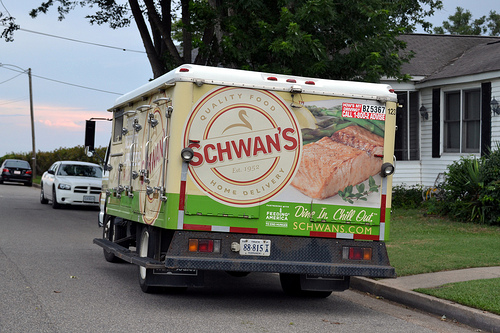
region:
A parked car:
[40, 159, 107, 204]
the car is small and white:
[40, 159, 106, 206]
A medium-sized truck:
[98, 83, 395, 298]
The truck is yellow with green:
[101, 76, 396, 301]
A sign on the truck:
[189, 88, 389, 211]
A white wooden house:
[379, 31, 499, 212]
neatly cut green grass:
[387, 207, 499, 302]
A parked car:
[2, 156, 29, 185]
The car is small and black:
[0, 157, 32, 184]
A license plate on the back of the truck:
[234, 236, 275, 257]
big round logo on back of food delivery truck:
[184, 88, 300, 205]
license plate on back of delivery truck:
[237, 235, 272, 259]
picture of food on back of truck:
[298, 139, 383, 195]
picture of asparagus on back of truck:
[297, 101, 340, 142]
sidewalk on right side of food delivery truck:
[398, 260, 498, 305]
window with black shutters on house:
[429, 84, 496, 161]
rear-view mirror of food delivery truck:
[80, 111, 112, 161]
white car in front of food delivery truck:
[39, 157, 102, 214]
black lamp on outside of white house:
[417, 101, 434, 125]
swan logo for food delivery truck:
[223, 105, 257, 132]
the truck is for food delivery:
[78, 63, 403, 301]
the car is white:
[33, 153, 111, 218]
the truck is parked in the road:
[83, 60, 406, 302]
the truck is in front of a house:
[76, 61, 401, 299]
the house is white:
[354, 67, 499, 210]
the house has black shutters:
[389, 81, 497, 160]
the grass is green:
[358, 203, 499, 327]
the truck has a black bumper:
[155, 227, 400, 284]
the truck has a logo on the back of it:
[180, 83, 303, 209]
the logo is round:
[184, 77, 301, 209]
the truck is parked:
[76, 47, 426, 316]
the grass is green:
[410, 221, 452, 274]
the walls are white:
[414, 85, 496, 172]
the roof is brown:
[403, 37, 491, 85]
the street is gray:
[3, 211, 106, 321]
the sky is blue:
[24, 34, 80, 81]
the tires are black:
[96, 214, 185, 314]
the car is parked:
[29, 146, 124, 230]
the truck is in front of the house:
[61, 29, 478, 326]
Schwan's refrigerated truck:
[95, 60, 430, 317]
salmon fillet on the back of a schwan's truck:
[293, 127, 385, 205]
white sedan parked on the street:
[35, 153, 108, 218]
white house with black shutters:
[411, 48, 498, 207]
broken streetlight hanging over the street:
[76, 105, 106, 158]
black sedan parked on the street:
[3, 155, 31, 190]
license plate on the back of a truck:
[233, 233, 278, 264]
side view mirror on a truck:
[76, 108, 105, 176]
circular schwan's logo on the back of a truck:
[183, 86, 306, 216]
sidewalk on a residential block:
[398, 252, 499, 279]